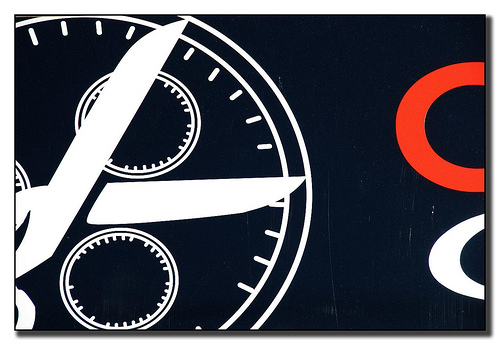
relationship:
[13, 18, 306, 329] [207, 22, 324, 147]
scissors over circle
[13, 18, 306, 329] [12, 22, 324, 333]
scissors within circle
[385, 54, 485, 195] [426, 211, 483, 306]
red curve over white curve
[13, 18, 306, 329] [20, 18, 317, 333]
scissors on a clock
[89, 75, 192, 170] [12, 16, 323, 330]
hash marks on inside of a gauge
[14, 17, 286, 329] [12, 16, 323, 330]
hash marks on inside of a gauge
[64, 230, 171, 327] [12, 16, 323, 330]
hash marks on inside of a gauge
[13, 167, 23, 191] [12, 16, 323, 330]
hash marks on inside of a gauge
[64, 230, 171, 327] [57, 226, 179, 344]
hash marks around circle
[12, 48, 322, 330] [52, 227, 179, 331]
gauge in bigger gauge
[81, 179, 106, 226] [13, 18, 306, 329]
shadow on scissors